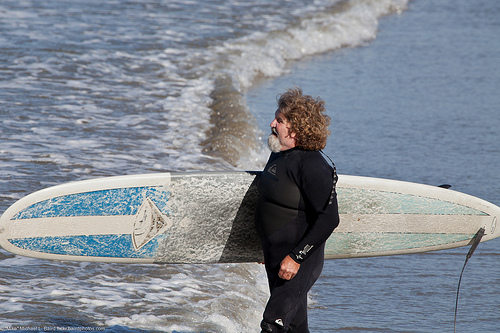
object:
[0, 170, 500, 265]
surf board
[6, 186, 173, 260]
blue and white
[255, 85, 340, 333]
man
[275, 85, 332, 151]
curly hair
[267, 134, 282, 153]
beard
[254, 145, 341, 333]
wetsuit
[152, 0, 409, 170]
wave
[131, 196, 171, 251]
emblem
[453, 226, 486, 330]
tether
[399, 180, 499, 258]
tie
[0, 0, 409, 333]
ocean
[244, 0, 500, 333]
beach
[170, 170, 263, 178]
edge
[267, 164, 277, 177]
logo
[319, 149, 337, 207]
strap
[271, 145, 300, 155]
neck